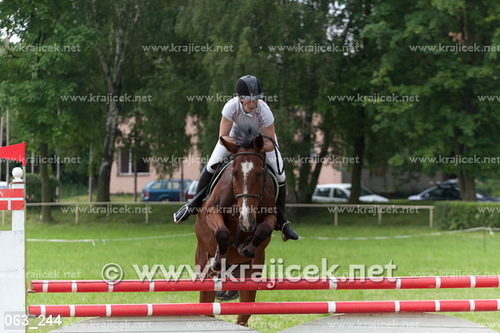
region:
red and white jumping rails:
[27, 274, 498, 315]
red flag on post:
[1, 139, 31, 164]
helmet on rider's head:
[235, 71, 265, 99]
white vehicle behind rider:
[307, 181, 389, 213]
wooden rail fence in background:
[307, 202, 438, 227]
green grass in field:
[355, 247, 498, 270]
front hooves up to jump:
[205, 205, 280, 269]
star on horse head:
[238, 159, 255, 223]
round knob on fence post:
[12, 164, 26, 184]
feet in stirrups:
[172, 202, 305, 243]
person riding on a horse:
[163, 52, 300, 332]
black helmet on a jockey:
[233, 58, 269, 112]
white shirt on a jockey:
[217, 92, 279, 165]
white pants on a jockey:
[206, 142, 293, 189]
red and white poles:
[113, 271, 360, 323]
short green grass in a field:
[318, 248, 382, 263]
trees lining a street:
[93, 53, 397, 197]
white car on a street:
[318, 167, 384, 217]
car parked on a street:
[406, 173, 499, 207]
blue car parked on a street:
[136, 178, 193, 205]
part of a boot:
[283, 216, 292, 250]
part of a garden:
[368, 230, 369, 237]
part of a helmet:
[241, 78, 259, 95]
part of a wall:
[355, 278, 365, 298]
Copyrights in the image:
[2, 36, 490, 231]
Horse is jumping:
[166, 141, 311, 327]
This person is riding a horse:
[166, 68, 316, 248]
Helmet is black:
[219, 71, 269, 111]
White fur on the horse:
[229, 153, 262, 235]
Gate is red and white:
[26, 254, 496, 323]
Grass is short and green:
[363, 239, 475, 272]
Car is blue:
[136, 170, 191, 205]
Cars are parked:
[131, 165, 499, 219]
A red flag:
[5, 131, 47, 212]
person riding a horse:
[166, 62, 301, 328]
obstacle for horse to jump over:
[27, 268, 495, 318]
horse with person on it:
[186, 134, 311, 314]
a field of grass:
[56, 228, 496, 300]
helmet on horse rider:
[233, 73, 263, 95]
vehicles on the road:
[309, 176, 486, 201]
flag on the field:
[2, 136, 32, 170]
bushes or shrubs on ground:
[426, 188, 499, 233]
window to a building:
[115, 149, 150, 171]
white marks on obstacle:
[318, 274, 349, 316]